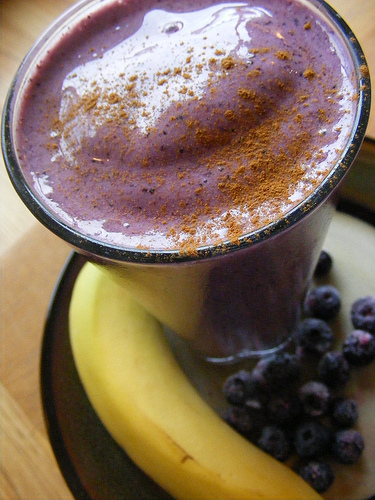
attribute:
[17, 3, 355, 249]
smoothy — purple, health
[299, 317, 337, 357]
blueberry — piled, blue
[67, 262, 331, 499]
banana — yellow, unpeeled, bright, spotted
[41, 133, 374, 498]
plate — round, earth, white, black, orage, gree, dark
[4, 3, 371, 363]
glass — tall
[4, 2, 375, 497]
table — wood